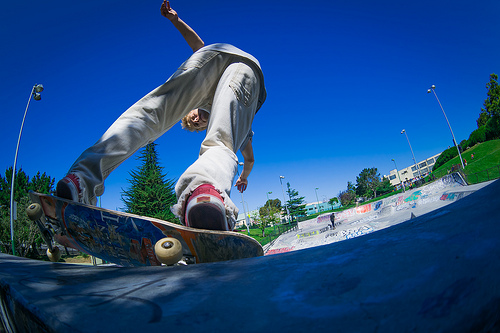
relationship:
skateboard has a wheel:
[26, 191, 265, 266] [155, 238, 182, 264]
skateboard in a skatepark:
[26, 191, 265, 266] [2, 174, 499, 331]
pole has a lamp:
[431, 89, 464, 169] [425, 84, 435, 93]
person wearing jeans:
[330, 213, 336, 230] [67, 50, 262, 231]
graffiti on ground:
[405, 189, 421, 203] [267, 170, 493, 254]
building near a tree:
[381, 153, 439, 190] [120, 143, 179, 225]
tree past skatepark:
[120, 143, 179, 225] [2, 174, 499, 331]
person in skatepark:
[328, 213, 335, 229] [2, 174, 499, 331]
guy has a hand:
[57, 0, 267, 232] [159, 2, 180, 21]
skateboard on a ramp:
[26, 191, 265, 266] [0, 170, 498, 333]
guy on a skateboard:
[57, 0, 267, 232] [26, 191, 265, 266]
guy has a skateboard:
[57, 0, 267, 232] [26, 191, 265, 266]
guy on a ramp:
[57, 0, 267, 232] [0, 170, 498, 333]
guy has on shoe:
[57, 0, 267, 232] [184, 183, 229, 231]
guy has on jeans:
[57, 0, 267, 232] [67, 50, 262, 231]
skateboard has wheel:
[26, 191, 265, 266] [155, 238, 182, 264]